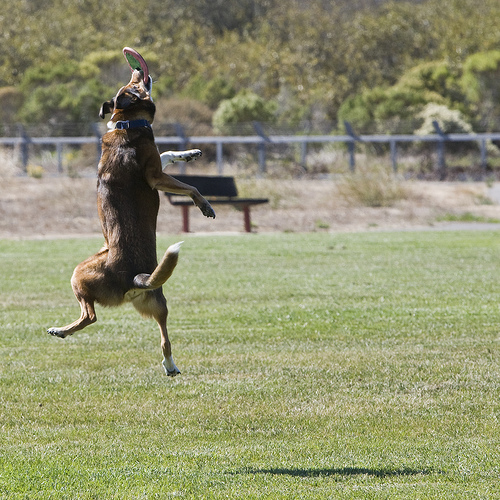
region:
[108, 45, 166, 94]
red and green frizbee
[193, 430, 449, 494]
shadow on the grass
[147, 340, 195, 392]
white and brown dog paw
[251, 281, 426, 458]
green and brown grass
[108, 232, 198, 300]
brown dog tail with white tip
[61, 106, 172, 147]
blue and silver dog collar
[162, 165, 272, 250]
bench near the grass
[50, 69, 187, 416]
brown and white dog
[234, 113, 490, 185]
tall silver fence with grass under it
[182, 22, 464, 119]
a bunch of trees with leaves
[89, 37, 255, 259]
the dog is jumping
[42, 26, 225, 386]
dog catching a frisbee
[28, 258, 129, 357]
hind leg of a dog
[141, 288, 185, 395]
hind leg of a dog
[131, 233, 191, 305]
dog tail with white tip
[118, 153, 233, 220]
front leg of a dog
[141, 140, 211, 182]
front leg of a dog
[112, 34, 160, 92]
green and pink frisbee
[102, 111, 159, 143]
collar on a dog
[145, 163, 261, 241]
bench in a field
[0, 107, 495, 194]
metal fence near a field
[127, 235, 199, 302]
the tail on a dog.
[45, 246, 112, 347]
the left leg of a dog.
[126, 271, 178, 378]
the right leg of a dog.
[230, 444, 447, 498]
a shadow cast by a dog.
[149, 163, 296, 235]
a wooden bench in a field.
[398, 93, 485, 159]
a large green bush.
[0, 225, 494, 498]
a field of green grass.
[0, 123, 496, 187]
a long fence in a field.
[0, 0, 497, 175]
a forest of wild plant growth.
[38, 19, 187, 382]
a dog with a frisbee in it's mouth.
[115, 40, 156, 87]
a frisbee in a dog's mouth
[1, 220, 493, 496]
green grass at a park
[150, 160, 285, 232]
a park bench by a field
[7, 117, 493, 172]
a fence around a park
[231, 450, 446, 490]
the shadow of dog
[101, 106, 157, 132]
a blue collar on a dog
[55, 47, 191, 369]
a brown dog jumping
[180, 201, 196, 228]
a red post supporting a bench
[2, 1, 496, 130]
trees behind a fence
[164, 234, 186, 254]
a white tip on a dog's tail